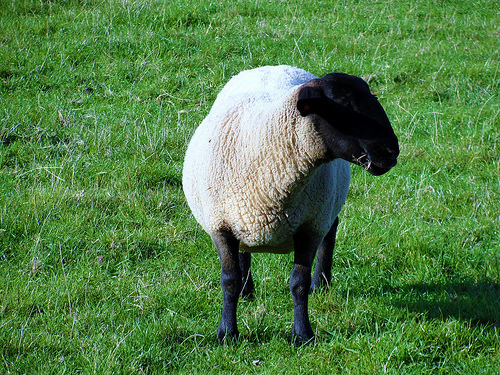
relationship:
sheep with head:
[181, 65, 403, 348] [296, 72, 402, 178]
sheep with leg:
[181, 65, 403, 348] [290, 229, 318, 345]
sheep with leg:
[181, 65, 403, 348] [313, 220, 338, 286]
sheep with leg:
[181, 65, 403, 348] [213, 230, 244, 342]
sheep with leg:
[181, 65, 403, 348] [239, 249, 259, 302]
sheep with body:
[181, 65, 403, 348] [180, 65, 309, 234]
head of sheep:
[296, 72, 402, 178] [181, 65, 403, 348]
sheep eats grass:
[181, 65, 403, 348] [353, 152, 376, 181]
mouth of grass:
[364, 151, 397, 170] [353, 152, 376, 181]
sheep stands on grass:
[181, 65, 403, 348] [1, 266, 499, 372]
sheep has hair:
[181, 65, 403, 348] [233, 87, 283, 139]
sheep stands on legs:
[181, 65, 403, 348] [210, 218, 338, 347]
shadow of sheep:
[234, 280, 499, 343] [181, 65, 403, 348]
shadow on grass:
[234, 280, 499, 343] [353, 152, 376, 181]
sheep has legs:
[181, 65, 403, 348] [210, 218, 338, 347]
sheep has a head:
[181, 65, 403, 348] [296, 72, 402, 178]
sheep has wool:
[181, 65, 403, 348] [223, 97, 278, 219]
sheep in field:
[181, 65, 403, 348] [2, 2, 496, 373]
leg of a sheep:
[313, 220, 338, 286] [181, 65, 403, 348]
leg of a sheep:
[239, 249, 259, 302] [181, 65, 403, 348]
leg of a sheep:
[213, 230, 244, 342] [181, 65, 403, 348]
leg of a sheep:
[290, 229, 318, 345] [181, 65, 403, 348]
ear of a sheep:
[296, 82, 322, 119] [181, 65, 403, 348]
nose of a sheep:
[384, 142, 402, 159] [181, 65, 403, 348]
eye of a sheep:
[337, 96, 354, 111] [181, 65, 403, 348]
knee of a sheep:
[292, 281, 311, 301] [181, 65, 403, 348]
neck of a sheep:
[294, 82, 327, 173] [181, 65, 403, 348]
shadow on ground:
[234, 280, 499, 343] [6, 226, 498, 353]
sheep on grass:
[181, 65, 403, 348] [1, 266, 499, 372]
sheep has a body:
[181, 65, 403, 348] [180, 65, 309, 234]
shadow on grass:
[234, 280, 499, 343] [1, 266, 499, 372]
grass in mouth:
[353, 152, 376, 181] [364, 151, 397, 170]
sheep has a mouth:
[181, 65, 403, 348] [364, 151, 397, 170]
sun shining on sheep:
[230, 76, 292, 102] [181, 65, 403, 348]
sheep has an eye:
[181, 65, 403, 348] [337, 96, 354, 111]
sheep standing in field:
[181, 65, 403, 348] [2, 2, 496, 373]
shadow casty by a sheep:
[234, 280, 499, 343] [181, 65, 403, 348]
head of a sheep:
[296, 72, 402, 178] [181, 65, 403, 348]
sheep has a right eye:
[181, 65, 403, 348] [337, 96, 354, 111]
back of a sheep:
[329, 164, 352, 224] [181, 65, 403, 348]